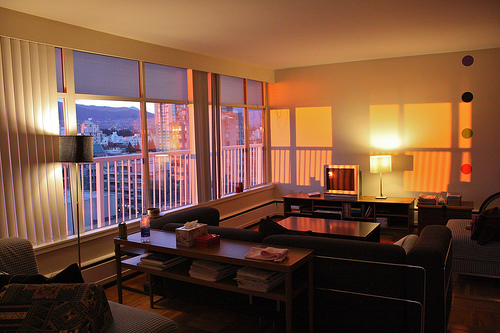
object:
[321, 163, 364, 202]
television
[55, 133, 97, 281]
floor lamp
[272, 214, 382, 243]
coffee table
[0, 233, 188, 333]
sofa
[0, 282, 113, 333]
items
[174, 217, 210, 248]
box of tissues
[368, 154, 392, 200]
lamp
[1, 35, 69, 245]
blinds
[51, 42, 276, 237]
view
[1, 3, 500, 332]
apartment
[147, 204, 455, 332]
sofa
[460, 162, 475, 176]
circular discs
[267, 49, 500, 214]
wall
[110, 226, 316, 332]
table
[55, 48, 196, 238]
window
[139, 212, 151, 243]
water bottle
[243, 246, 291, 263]
cloth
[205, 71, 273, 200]
window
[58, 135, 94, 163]
shade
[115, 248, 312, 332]
shelf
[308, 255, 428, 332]
metal frame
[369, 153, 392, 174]
shade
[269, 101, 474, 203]
sunset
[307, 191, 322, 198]
remote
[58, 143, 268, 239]
railing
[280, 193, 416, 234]
table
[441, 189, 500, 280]
chair